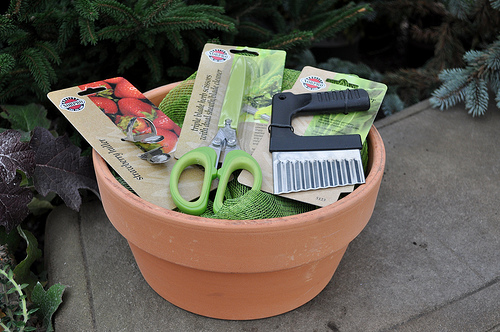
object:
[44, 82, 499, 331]
bench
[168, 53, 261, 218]
shears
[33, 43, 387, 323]
planter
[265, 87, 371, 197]
tool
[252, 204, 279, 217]
mesh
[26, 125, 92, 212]
plant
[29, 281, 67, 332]
plant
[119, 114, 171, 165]
tool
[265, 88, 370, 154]
handle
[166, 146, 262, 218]
handle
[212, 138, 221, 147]
screw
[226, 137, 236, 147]
screw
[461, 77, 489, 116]
pine branch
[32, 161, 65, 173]
line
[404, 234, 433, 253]
spot